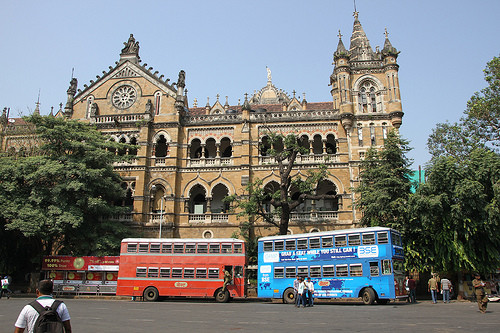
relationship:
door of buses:
[221, 256, 248, 307] [37, 220, 414, 310]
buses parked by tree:
[37, 220, 414, 310] [0, 108, 132, 293]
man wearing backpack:
[14, 279, 71, 331] [26, 297, 65, 332]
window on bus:
[121, 243, 133, 254] [104, 232, 261, 313]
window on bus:
[231, 238, 243, 257] [104, 232, 261, 313]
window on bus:
[146, 238, 163, 255] [104, 232, 261, 313]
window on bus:
[180, 239, 197, 256] [104, 232, 261, 313]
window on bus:
[205, 238, 224, 257] [104, 232, 261, 313]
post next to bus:
[150, 192, 173, 236] [246, 226, 422, 311]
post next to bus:
[150, 192, 173, 236] [106, 225, 255, 305]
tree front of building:
[0, 98, 132, 293] [6, 0, 439, 281]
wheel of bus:
[277, 286, 299, 304] [252, 227, 410, 302]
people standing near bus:
[296, 275, 305, 303] [254, 221, 413, 307]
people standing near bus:
[303, 277, 315, 307] [254, 221, 413, 307]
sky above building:
[37, 22, 475, 224] [42, 37, 497, 301]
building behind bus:
[56, 33, 467, 324] [255, 223, 407, 305]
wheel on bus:
[215, 288, 228, 301] [115, 235, 249, 302]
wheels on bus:
[134, 283, 226, 302] [114, 222, 254, 306]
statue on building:
[260, 65, 272, 82] [3, 13, 404, 238]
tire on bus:
[359, 285, 376, 306] [254, 221, 413, 307]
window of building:
[117, 74, 170, 126] [85, 53, 481, 254]